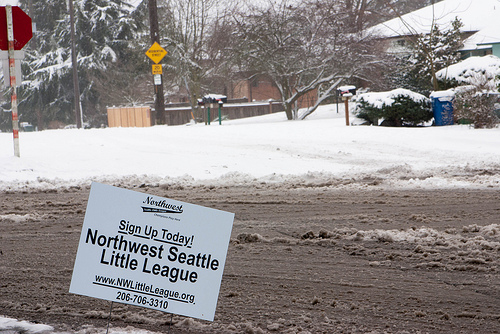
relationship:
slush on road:
[321, 221, 445, 266] [0, 191, 498, 333]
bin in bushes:
[432, 91, 454, 126] [354, 84, 436, 128]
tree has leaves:
[1, 1, 187, 125] [87, 15, 116, 38]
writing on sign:
[117, 214, 196, 247] [70, 181, 237, 323]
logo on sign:
[140, 195, 186, 217] [70, 181, 237, 323]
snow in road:
[0, 102, 500, 192] [0, 191, 498, 333]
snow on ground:
[0, 102, 500, 192] [1, 102, 499, 334]